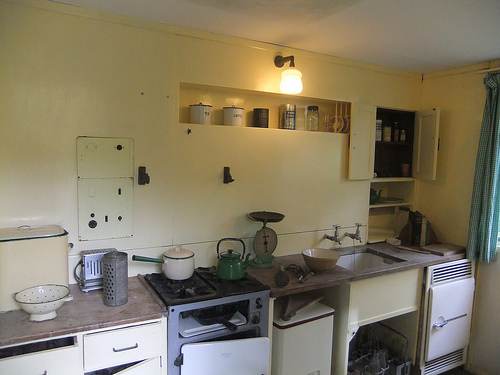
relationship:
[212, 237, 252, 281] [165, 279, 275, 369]
tea kettle on stove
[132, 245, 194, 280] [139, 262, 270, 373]
pot on stove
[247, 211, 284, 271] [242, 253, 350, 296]
scale on counter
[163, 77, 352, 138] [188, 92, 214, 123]
built-in shelf with containers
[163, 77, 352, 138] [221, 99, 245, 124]
built-in shelf with containers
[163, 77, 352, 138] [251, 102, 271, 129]
built-in shelf with containers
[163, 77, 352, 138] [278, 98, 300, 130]
built-in shelf with containers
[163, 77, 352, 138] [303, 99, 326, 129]
built-in shelf with containers